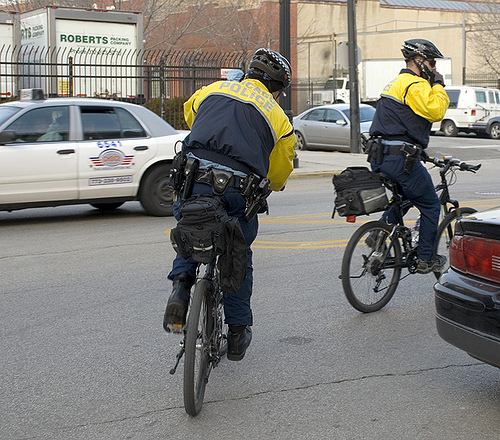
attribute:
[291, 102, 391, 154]
car — grey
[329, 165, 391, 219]
pack — black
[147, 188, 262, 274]
bag — black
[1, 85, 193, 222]
car — white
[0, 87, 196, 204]
car — white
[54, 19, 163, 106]
door — part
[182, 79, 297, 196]
jacket — yellow and blue, black and yellow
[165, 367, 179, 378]
stand — part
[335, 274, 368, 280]
stand — part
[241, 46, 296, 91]
helmet — black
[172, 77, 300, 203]
jacket — yellow and blue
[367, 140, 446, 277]
pants — black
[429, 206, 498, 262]
light — red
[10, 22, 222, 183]
car — grey and white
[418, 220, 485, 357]
car — black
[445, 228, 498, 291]
rear light — red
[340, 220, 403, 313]
tire — black, round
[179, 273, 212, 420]
tire — round, black